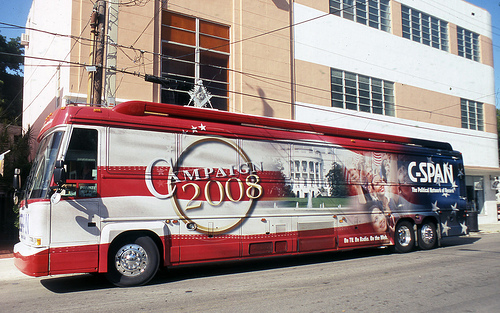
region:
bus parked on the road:
[21, 90, 479, 300]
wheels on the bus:
[107, 223, 165, 299]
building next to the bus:
[103, 2, 496, 168]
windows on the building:
[311, 49, 405, 109]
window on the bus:
[23, 129, 110, 206]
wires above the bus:
[11, 5, 260, 105]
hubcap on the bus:
[111, 245, 158, 290]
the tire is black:
[103, 228, 185, 310]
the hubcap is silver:
[106, 228, 177, 305]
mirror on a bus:
[41, 148, 97, 198]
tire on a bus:
[111, 215, 176, 301]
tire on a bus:
[391, 210, 416, 257]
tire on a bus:
[420, 212, 445, 253]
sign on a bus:
[165, 137, 257, 244]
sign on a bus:
[406, 152, 466, 194]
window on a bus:
[61, 127, 104, 207]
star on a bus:
[453, 218, 470, 243]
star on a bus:
[433, 212, 455, 238]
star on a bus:
[442, 195, 461, 223]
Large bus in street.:
[6, 87, 484, 285]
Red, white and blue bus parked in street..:
[17, 98, 478, 277]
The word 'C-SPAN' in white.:
[404, 150, 456, 186]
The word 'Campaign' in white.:
[145, 157, 265, 199]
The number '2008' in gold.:
[180, 173, 262, 209]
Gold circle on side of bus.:
[157, 133, 264, 235]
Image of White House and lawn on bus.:
[275, 144, 350, 211]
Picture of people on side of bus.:
[348, 148, 400, 238]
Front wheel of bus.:
[90, 223, 174, 285]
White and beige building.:
[22, 0, 499, 237]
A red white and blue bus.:
[9, 98, 469, 288]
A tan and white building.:
[21, 0, 499, 222]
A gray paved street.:
[1, 231, 499, 311]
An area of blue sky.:
[1, 0, 33, 80]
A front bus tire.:
[107, 228, 161, 287]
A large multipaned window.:
[323, 68, 407, 118]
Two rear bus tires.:
[393, 213, 438, 252]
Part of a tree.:
[0, 30, 23, 77]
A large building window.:
[158, 10, 236, 109]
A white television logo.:
[407, 158, 457, 193]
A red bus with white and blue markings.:
[18, 101, 478, 288]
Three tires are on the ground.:
[108, 220, 437, 283]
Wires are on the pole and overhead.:
[1, 0, 496, 142]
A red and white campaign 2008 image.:
[144, 137, 264, 234]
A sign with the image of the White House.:
[277, 147, 335, 200]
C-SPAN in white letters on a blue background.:
[404, 160, 460, 184]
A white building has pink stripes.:
[21, 2, 493, 164]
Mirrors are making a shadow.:
[53, 123, 108, 235]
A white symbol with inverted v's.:
[183, 80, 218, 106]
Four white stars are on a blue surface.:
[429, 197, 472, 239]